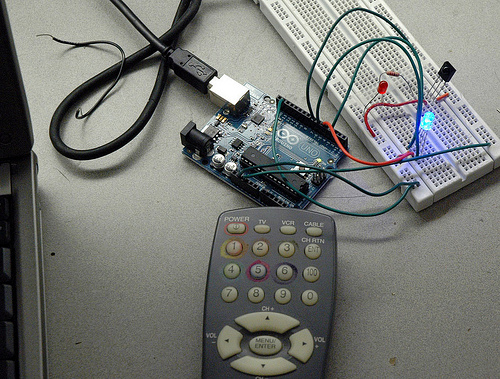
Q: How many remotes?
A: 1.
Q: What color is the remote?
A: Black.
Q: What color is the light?
A: Blue.